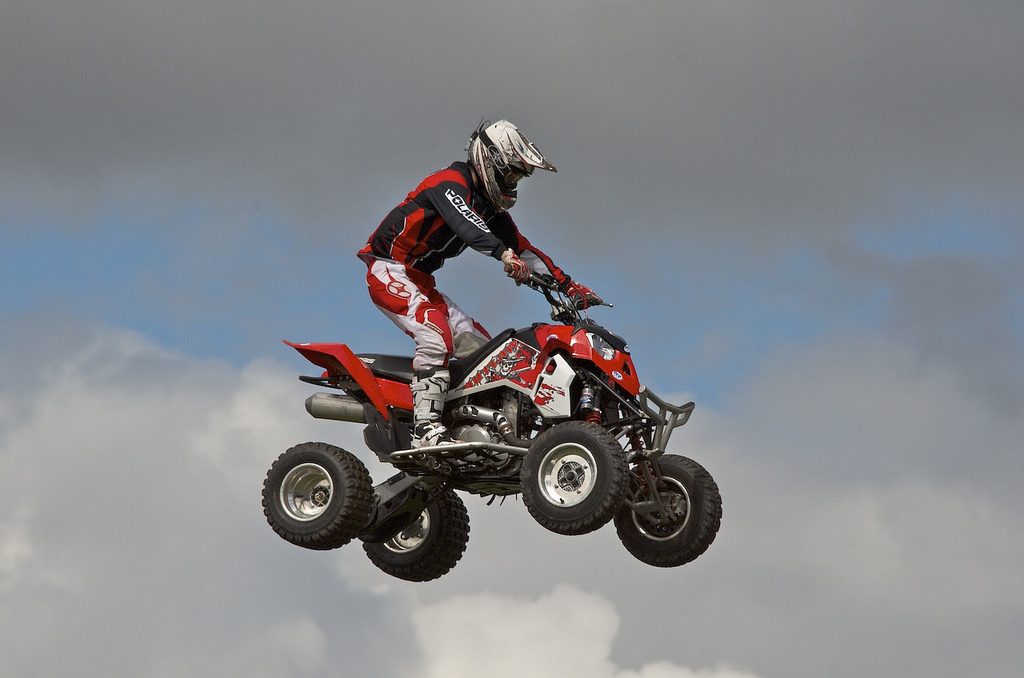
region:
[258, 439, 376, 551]
right rear wheel on quadracer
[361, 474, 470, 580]
left rear wheel on quadracer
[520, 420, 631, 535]
right front wheel on quadracer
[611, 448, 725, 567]
left front wheel on quadracer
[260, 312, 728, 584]
quadracer ridden by man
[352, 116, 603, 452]
man jumping quadracer through the air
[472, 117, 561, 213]
helmet worn by the man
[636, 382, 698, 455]
bumper bars on the quadracer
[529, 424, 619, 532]
black tire is round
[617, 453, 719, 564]
black tire is round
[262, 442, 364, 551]
black tire is round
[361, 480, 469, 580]
black tire is round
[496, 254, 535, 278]
person has a hand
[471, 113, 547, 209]
person has a white helmet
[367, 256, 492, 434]
pants are red and white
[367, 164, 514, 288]
shirt is red and black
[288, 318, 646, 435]
body is red and black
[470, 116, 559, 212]
a white and black helmet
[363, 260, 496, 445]
red and white colored pants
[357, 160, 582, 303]
a red, white, and black jackeet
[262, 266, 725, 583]
a red, white, and black four wheeler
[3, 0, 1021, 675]
a blue sky with white and gray clouds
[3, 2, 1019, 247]
gray clouds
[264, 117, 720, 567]
a person on a four wheeler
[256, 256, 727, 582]
a four wheeler in the air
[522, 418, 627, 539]
a round black tire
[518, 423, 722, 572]
two front tires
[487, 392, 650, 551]
wheel on the vehicle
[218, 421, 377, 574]
back tire of vehicle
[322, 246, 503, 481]
leg of the man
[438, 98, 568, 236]
helmet on the person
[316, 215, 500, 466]
pants of the person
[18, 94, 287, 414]
sky above the person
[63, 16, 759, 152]
rain clouds in sky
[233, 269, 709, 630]
four wheel object in air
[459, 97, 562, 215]
white plastic helmet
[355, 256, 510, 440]
white and red pants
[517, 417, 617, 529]
black tire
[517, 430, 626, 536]
A tire on a vehicle.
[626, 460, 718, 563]
A tire on a vehicle.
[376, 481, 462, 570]
A tire on a vehicle.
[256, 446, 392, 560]
A tire on a vehicle.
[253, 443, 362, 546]
A tire on an ATV.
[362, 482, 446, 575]
A tire on an ATV.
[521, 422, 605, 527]
A tire on an ATV.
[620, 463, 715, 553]
A tire on an ATV.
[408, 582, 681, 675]
A cloud in the sky.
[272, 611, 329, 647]
A cloud in the sky.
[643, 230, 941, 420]
a white fluffy cloud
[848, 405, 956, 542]
a white fluffy cloud